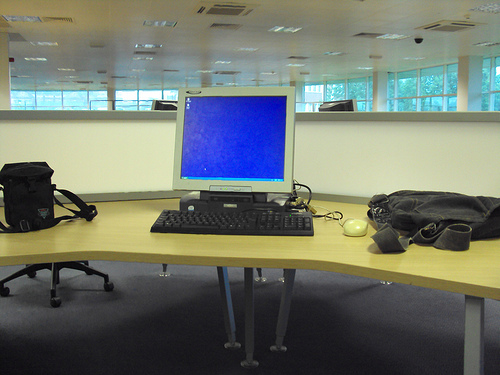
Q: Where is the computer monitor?
A: On the table.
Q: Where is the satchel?
A: To the right of the monitor on the desk.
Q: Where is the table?
A: In an office.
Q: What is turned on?
A: Computer screen.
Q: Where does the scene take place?
A: In an office.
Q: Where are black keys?
A: On keyboard.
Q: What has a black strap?
A: Bag on left.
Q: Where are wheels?
A: Under a chair.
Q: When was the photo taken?
A: During the daytime.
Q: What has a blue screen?
A: Computer monitor.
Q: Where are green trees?
A: Outside the windows.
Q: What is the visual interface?
A: A monitor.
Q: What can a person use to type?
A: The keyboard.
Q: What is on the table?
A: A bag.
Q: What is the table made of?
A: Wood.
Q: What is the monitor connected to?
A: A computer.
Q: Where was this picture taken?
A: An office.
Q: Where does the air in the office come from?
A: The air vents.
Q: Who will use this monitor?
A: An employee.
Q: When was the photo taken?
A: Daytime.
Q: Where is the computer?
A: Desk.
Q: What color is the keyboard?
A: Black.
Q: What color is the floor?
A: Gray.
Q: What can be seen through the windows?
A: Trees.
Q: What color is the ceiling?
A: White.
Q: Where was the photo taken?
A: Office desk.